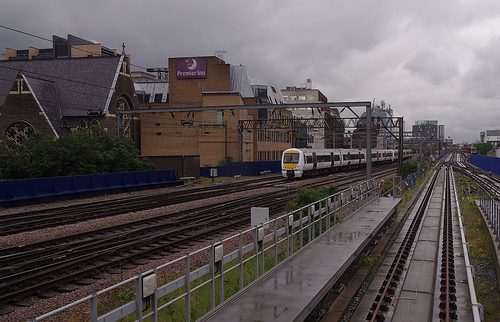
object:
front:
[281, 148, 304, 180]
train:
[280, 148, 412, 182]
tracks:
[0, 174, 397, 238]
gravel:
[0, 183, 206, 216]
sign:
[176, 57, 208, 79]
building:
[132, 48, 292, 167]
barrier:
[0, 169, 186, 208]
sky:
[0, 0, 500, 145]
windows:
[307, 156, 313, 163]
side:
[303, 149, 412, 176]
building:
[0, 33, 141, 158]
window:
[3, 120, 39, 159]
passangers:
[317, 150, 324, 168]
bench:
[191, 196, 403, 322]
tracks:
[360, 151, 462, 322]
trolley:
[462, 146, 478, 155]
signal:
[114, 101, 374, 194]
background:
[0, 0, 500, 166]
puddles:
[316, 230, 370, 246]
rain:
[0, 0, 497, 151]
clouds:
[401, 48, 458, 85]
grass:
[84, 160, 440, 322]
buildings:
[280, 78, 346, 151]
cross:
[122, 42, 126, 52]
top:
[0, 54, 126, 62]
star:
[185, 59, 189, 63]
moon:
[187, 58, 198, 71]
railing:
[25, 175, 381, 321]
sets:
[0, 152, 500, 322]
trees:
[0, 130, 67, 179]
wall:
[0, 155, 202, 181]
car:
[339, 147, 366, 171]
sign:
[210, 169, 218, 177]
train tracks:
[0, 163, 414, 322]